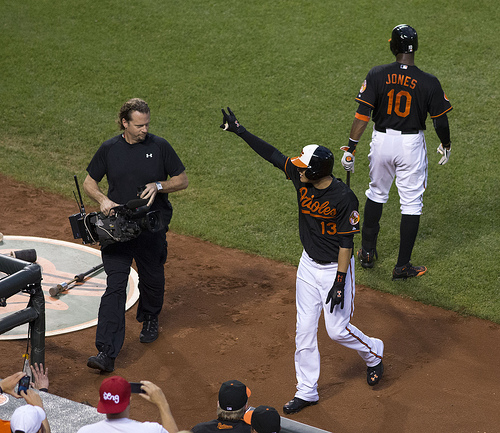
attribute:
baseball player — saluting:
[212, 105, 387, 416]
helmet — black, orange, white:
[290, 143, 334, 181]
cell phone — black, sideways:
[127, 383, 147, 394]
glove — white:
[442, 136, 474, 173]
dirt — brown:
[203, 289, 264, 336]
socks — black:
[354, 191, 421, 270]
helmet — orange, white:
[290, 144, 334, 178]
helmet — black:
[387, 24, 419, 54]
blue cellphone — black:
[15, 374, 31, 396]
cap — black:
[381, 16, 420, 51]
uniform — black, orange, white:
[219, 109, 401, 406]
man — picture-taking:
[75, 373, 178, 431]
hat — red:
[95, 376, 129, 413]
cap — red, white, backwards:
[78, 377, 140, 427]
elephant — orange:
[353, 60, 459, 138]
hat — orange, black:
[287, 143, 339, 176]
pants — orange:
[283, 252, 391, 404]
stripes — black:
[338, 260, 388, 365]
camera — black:
[78, 199, 177, 254]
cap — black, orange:
[273, 119, 349, 178]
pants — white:
[361, 129, 428, 213]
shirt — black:
[364, 56, 449, 130]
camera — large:
[67, 197, 160, 254]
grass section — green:
[3, 0, 499, 318]